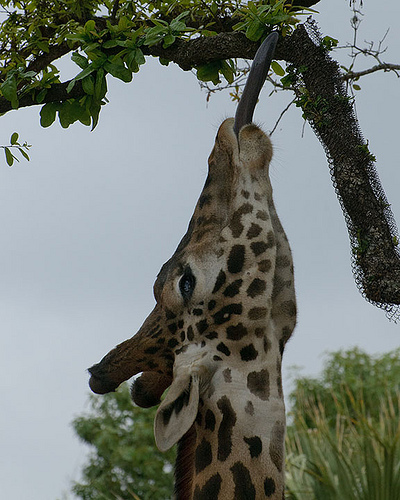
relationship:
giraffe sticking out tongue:
[86, 25, 313, 500] [223, 26, 279, 131]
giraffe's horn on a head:
[90, 327, 166, 409] [67, 110, 309, 420]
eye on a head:
[175, 268, 197, 304] [82, 116, 295, 389]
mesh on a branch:
[330, 106, 378, 218] [280, 18, 385, 295]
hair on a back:
[171, 430, 193, 492] [170, 343, 282, 498]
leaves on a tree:
[3, 1, 179, 123] [0, 4, 365, 129]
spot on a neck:
[214, 394, 240, 466] [163, 336, 292, 496]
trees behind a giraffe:
[283, 342, 384, 493] [86, 25, 313, 500]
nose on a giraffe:
[200, 142, 225, 164] [86, 25, 313, 500]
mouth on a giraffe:
[199, 109, 280, 175] [86, 25, 313, 500]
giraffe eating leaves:
[86, 25, 313, 500] [3, 2, 331, 144]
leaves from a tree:
[3, 2, 331, 144] [0, 4, 365, 129]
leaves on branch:
[48, 2, 300, 100] [7, 0, 387, 123]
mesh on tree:
[285, 29, 378, 211] [2, 0, 397, 311]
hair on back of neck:
[171, 430, 193, 492] [150, 344, 286, 491]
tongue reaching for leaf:
[218, 27, 278, 125] [230, 4, 307, 35]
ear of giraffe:
[141, 362, 217, 462] [86, 25, 313, 500]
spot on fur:
[238, 365, 274, 402] [212, 347, 284, 489]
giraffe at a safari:
[86, 25, 313, 500] [70, 343, 387, 479]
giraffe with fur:
[86, 25, 313, 500] [198, 400, 290, 491]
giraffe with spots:
[86, 25, 313, 500] [210, 202, 275, 471]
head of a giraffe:
[82, 116, 295, 389] [86, 25, 313, 500]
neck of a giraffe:
[160, 352, 288, 498] [86, 25, 313, 500]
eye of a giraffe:
[175, 268, 197, 304] [86, 25, 313, 500]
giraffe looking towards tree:
[86, 25, 313, 500] [0, 3, 378, 101]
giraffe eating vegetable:
[86, 25, 313, 500] [219, 22, 290, 132]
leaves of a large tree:
[0, 5, 320, 85] [1, 2, 384, 324]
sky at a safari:
[3, 118, 205, 225] [7, 0, 398, 496]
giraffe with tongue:
[86, 25, 313, 500] [218, 27, 278, 125]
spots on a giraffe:
[212, 216, 284, 378] [86, 25, 313, 500]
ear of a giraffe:
[151, 362, 203, 457] [86, 25, 313, 500]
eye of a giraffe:
[174, 256, 198, 319] [86, 25, 313, 500]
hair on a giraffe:
[171, 430, 193, 492] [86, 25, 313, 500]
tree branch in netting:
[272, 24, 384, 316] [310, 82, 384, 226]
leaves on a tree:
[0, 8, 118, 133] [0, 8, 357, 86]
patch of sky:
[111, 107, 196, 191] [3, 3, 383, 161]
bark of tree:
[200, 47, 246, 60] [0, 3, 378, 101]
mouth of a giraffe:
[199, 109, 280, 175] [86, 25, 313, 500]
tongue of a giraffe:
[218, 27, 278, 125] [86, 25, 313, 500]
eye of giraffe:
[175, 268, 197, 304] [86, 25, 313, 500]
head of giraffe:
[82, 116, 295, 389] [86, 25, 313, 500]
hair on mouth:
[253, 120, 271, 141] [192, 113, 281, 172]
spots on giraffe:
[222, 216, 282, 458] [86, 25, 313, 500]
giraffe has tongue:
[86, 29, 311, 493] [229, 26, 281, 127]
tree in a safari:
[0, 3, 378, 101] [7, 0, 398, 496]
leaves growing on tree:
[16, 21, 148, 130] [2, 0, 397, 311]